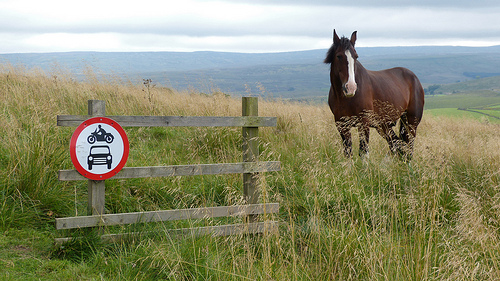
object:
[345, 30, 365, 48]
ears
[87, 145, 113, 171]
car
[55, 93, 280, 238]
wooden fence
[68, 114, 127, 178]
round sign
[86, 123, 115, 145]
motorcycle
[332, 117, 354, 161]
leg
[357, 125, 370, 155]
leg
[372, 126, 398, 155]
leg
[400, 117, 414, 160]
leg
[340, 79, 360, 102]
nose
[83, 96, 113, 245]
post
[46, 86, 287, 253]
fence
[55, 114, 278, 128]
post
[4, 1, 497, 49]
gray sky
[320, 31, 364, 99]
head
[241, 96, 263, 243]
post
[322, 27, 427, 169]
horse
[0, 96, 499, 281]
grass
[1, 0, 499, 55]
sky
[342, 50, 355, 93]
face